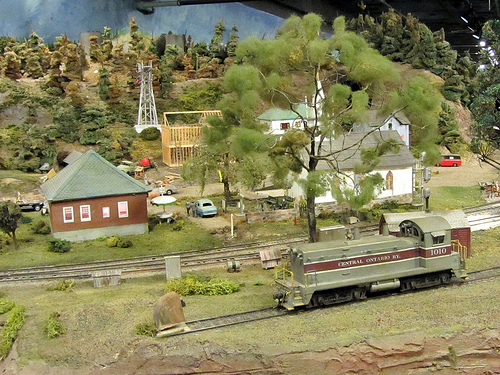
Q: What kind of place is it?
A: It is a town.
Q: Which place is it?
A: It is a town.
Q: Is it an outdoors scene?
A: Yes, it is outdoors.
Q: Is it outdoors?
A: Yes, it is outdoors.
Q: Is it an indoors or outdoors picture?
A: It is outdoors.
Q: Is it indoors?
A: No, it is outdoors.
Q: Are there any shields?
A: No, there are no shields.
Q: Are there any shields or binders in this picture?
A: No, there are no shields or binders.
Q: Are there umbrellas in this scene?
A: Yes, there is an umbrella.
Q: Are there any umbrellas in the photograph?
A: Yes, there is an umbrella.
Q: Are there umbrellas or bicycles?
A: Yes, there is an umbrella.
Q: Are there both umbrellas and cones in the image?
A: No, there is an umbrella but no cones.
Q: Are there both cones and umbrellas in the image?
A: No, there is an umbrella but no cones.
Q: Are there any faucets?
A: No, there are no faucets.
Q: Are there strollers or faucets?
A: No, there are no faucets or strollers.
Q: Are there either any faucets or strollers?
A: No, there are no faucets or strollers.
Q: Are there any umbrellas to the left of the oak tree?
A: Yes, there is an umbrella to the left of the oak tree.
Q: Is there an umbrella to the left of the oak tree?
A: Yes, there is an umbrella to the left of the oak tree.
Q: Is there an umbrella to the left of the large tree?
A: Yes, there is an umbrella to the left of the oak tree.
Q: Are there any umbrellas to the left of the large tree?
A: Yes, there is an umbrella to the left of the oak tree.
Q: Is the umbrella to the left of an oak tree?
A: Yes, the umbrella is to the left of an oak tree.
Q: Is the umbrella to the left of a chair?
A: No, the umbrella is to the left of an oak tree.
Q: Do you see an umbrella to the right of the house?
A: Yes, there is an umbrella to the right of the house.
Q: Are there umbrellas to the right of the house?
A: Yes, there is an umbrella to the right of the house.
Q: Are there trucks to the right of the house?
A: No, there is an umbrella to the right of the house.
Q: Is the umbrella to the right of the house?
A: Yes, the umbrella is to the right of the house.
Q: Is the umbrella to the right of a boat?
A: No, the umbrella is to the right of the house.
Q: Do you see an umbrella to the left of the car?
A: Yes, there is an umbrella to the left of the car.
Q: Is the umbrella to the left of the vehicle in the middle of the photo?
A: Yes, the umbrella is to the left of the car.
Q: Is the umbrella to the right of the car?
A: No, the umbrella is to the left of the car.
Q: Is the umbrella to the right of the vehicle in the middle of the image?
A: No, the umbrella is to the left of the car.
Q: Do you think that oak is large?
A: Yes, the oak is large.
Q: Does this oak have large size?
A: Yes, the oak is large.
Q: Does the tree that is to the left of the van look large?
A: Yes, the oak is large.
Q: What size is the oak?
A: The oak is large.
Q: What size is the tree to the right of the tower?
A: The oak is large.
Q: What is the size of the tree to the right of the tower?
A: The oak is large.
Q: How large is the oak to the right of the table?
A: The oak tree is large.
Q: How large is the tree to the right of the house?
A: The oak tree is large.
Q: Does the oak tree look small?
A: No, the oak tree is large.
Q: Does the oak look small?
A: No, the oak is large.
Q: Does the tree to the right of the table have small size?
A: No, the oak is large.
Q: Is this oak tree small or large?
A: The oak tree is large.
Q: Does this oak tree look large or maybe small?
A: The oak tree is large.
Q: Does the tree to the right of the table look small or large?
A: The oak tree is large.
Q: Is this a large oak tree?
A: Yes, this is a large oak tree.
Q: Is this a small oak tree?
A: No, this is a large oak tree.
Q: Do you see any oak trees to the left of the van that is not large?
A: Yes, there is an oak tree to the left of the van.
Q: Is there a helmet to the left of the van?
A: No, there is an oak tree to the left of the van.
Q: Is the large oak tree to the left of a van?
A: Yes, the oak is to the left of a van.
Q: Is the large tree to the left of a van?
A: Yes, the oak is to the left of a van.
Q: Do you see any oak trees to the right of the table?
A: Yes, there is an oak tree to the right of the table.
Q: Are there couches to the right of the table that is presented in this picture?
A: No, there is an oak tree to the right of the table.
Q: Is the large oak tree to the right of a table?
A: Yes, the oak tree is to the right of a table.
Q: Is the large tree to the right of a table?
A: Yes, the oak tree is to the right of a table.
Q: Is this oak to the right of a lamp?
A: No, the oak is to the right of a table.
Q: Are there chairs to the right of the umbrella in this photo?
A: No, there is an oak tree to the right of the umbrella.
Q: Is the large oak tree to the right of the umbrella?
A: Yes, the oak tree is to the right of the umbrella.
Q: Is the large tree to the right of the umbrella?
A: Yes, the oak tree is to the right of the umbrella.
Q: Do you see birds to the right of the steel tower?
A: No, there is an oak tree to the right of the tower.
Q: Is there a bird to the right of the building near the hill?
A: No, there is an oak tree to the right of the tower.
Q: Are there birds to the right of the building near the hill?
A: No, there is an oak tree to the right of the tower.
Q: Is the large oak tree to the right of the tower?
A: Yes, the oak tree is to the right of the tower.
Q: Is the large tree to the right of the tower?
A: Yes, the oak tree is to the right of the tower.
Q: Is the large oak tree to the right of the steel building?
A: Yes, the oak tree is to the right of the tower.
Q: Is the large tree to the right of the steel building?
A: Yes, the oak tree is to the right of the tower.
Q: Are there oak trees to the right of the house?
A: Yes, there is an oak tree to the right of the house.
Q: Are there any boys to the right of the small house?
A: No, there is an oak tree to the right of the house.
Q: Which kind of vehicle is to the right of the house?
A: The vehicle is a car.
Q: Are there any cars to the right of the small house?
A: Yes, there is a car to the right of the house.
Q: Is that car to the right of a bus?
A: No, the car is to the right of the house.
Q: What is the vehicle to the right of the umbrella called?
A: The vehicle is a car.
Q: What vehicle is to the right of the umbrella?
A: The vehicle is a car.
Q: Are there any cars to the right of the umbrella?
A: Yes, there is a car to the right of the umbrella.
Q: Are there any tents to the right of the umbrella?
A: No, there is a car to the right of the umbrella.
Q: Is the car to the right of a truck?
A: No, the car is to the right of the umbrella.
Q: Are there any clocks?
A: No, there are no clocks.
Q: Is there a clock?
A: No, there are no clocks.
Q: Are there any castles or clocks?
A: No, there are no clocks or castles.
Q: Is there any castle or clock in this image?
A: No, there are no clocks or castles.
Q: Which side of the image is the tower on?
A: The tower is on the left of the image.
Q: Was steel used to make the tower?
A: Yes, the tower is made of steel.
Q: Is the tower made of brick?
A: No, the tower is made of steel.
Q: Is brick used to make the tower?
A: No, the tower is made of steel.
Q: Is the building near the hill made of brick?
A: No, the tower is made of steel.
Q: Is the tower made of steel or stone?
A: The tower is made of steel.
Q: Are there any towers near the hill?
A: Yes, there is a tower near the hill.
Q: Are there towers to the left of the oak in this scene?
A: Yes, there is a tower to the left of the oak.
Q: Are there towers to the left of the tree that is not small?
A: Yes, there is a tower to the left of the oak.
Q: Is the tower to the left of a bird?
A: No, the tower is to the left of the oak tree.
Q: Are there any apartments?
A: No, there are no apartments.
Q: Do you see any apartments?
A: No, there are no apartments.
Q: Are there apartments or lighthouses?
A: No, there are no apartments or lighthouses.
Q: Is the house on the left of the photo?
A: Yes, the house is on the left of the image.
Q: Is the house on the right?
A: No, the house is on the left of the image.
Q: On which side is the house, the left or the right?
A: The house is on the left of the image.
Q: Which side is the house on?
A: The house is on the left of the image.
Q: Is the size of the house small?
A: Yes, the house is small.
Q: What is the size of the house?
A: The house is small.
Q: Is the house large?
A: No, the house is small.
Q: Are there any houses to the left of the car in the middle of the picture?
A: Yes, there is a house to the left of the car.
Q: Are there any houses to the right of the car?
A: No, the house is to the left of the car.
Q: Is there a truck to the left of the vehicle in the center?
A: No, there is a house to the left of the car.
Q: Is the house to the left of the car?
A: Yes, the house is to the left of the car.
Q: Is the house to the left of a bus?
A: No, the house is to the left of the car.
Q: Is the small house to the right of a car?
A: No, the house is to the left of a car.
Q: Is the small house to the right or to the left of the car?
A: The house is to the left of the car.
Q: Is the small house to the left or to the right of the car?
A: The house is to the left of the car.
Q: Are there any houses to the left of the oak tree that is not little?
A: Yes, there is a house to the left of the oak tree.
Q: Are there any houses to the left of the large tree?
A: Yes, there is a house to the left of the oak tree.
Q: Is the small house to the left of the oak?
A: Yes, the house is to the left of the oak.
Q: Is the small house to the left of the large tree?
A: Yes, the house is to the left of the oak.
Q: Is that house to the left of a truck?
A: No, the house is to the left of the oak.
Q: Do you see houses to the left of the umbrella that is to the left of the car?
A: Yes, there is a house to the left of the umbrella.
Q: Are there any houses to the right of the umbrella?
A: No, the house is to the left of the umbrella.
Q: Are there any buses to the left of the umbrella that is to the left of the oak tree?
A: No, there is a house to the left of the umbrella.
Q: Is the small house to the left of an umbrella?
A: Yes, the house is to the left of an umbrella.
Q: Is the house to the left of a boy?
A: No, the house is to the left of an umbrella.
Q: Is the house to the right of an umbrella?
A: No, the house is to the left of an umbrella.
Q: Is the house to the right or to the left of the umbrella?
A: The house is to the left of the umbrella.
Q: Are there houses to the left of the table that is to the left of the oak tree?
A: Yes, there is a house to the left of the table.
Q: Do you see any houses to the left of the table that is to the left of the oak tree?
A: Yes, there is a house to the left of the table.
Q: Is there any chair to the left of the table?
A: No, there is a house to the left of the table.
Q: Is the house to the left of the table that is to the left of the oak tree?
A: Yes, the house is to the left of the table.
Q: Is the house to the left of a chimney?
A: No, the house is to the left of the table.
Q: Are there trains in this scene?
A: Yes, there is a train.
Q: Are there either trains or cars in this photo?
A: Yes, there is a train.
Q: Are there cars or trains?
A: Yes, there is a train.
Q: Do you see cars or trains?
A: Yes, there is a train.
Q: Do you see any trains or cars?
A: Yes, there is a train.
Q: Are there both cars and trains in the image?
A: Yes, there are both a train and a car.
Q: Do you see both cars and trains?
A: Yes, there are both a train and a car.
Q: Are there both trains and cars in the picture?
A: Yes, there are both a train and a car.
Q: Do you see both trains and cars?
A: Yes, there are both a train and a car.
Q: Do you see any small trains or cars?
A: Yes, there is a small train.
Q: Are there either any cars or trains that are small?
A: Yes, the train is small.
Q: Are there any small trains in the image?
A: Yes, there is a small train.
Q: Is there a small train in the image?
A: Yes, there is a small train.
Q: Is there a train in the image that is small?
A: Yes, there is a train that is small.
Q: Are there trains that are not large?
A: Yes, there is a small train.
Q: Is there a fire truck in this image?
A: No, there are no fire trucks.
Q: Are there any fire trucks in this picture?
A: No, there are no fire trucks.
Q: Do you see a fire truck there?
A: No, there are no fire trucks.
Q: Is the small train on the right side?
A: Yes, the train is on the right of the image.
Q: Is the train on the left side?
A: No, the train is on the right of the image.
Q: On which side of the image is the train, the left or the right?
A: The train is on the right of the image.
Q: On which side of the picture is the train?
A: The train is on the right of the image.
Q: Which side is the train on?
A: The train is on the right of the image.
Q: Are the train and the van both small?
A: Yes, both the train and the van are small.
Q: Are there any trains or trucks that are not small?
A: No, there is a train but it is small.